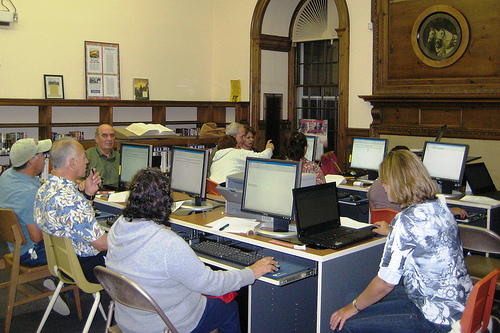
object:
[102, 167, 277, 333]
people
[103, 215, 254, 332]
sweater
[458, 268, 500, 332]
chair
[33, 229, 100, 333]
chair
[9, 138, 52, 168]
cap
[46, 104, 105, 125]
shelf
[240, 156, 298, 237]
computers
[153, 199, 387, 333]
desks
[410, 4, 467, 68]
design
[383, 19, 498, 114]
wall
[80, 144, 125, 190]
shirt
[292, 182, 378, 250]
laptop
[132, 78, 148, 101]
picture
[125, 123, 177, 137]
book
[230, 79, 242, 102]
paper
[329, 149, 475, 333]
lady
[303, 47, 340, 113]
window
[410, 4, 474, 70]
frame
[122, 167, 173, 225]
hair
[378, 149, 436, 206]
hair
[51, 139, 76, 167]
hair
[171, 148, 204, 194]
monitor